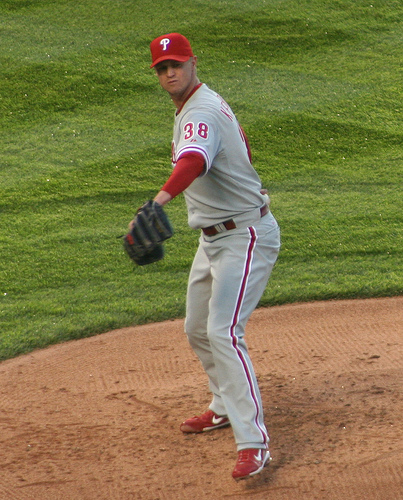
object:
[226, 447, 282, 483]
shoe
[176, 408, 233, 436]
shoe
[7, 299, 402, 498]
mound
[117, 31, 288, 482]
pitcher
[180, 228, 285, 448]
pants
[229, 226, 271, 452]
stripe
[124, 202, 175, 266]
glove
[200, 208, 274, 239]
belt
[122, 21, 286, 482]
man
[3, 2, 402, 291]
grass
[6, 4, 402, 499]
field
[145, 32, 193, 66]
cap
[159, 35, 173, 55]
logo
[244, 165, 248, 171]
gray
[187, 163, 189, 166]
red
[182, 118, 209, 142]
number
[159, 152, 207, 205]
shirt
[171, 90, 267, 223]
jersey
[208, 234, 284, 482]
leg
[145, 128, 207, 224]
arm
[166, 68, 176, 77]
nose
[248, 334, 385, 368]
track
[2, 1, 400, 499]
photo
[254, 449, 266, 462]
logo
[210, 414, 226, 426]
logo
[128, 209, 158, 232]
hand